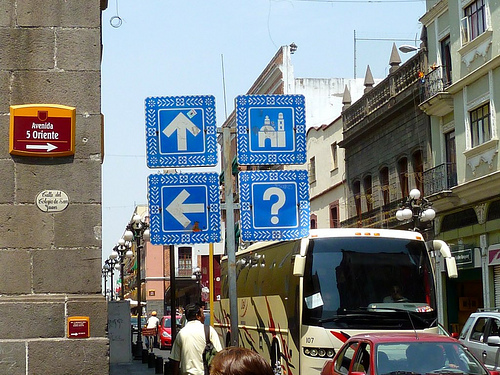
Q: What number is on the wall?
A: 5.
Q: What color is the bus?
A: White.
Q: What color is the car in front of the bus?
A: Red.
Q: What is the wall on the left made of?
A: Cinder block.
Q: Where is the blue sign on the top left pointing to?
A: Straight ahead.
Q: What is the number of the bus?
A: 107.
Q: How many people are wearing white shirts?
A: 2.